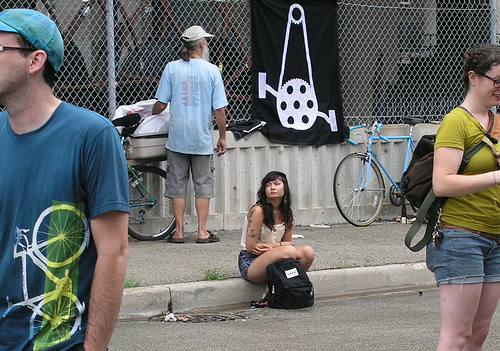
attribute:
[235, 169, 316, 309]
woman — sitting, looking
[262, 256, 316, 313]
backpack — black, sitting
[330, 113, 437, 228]
bicycle — blue, leaning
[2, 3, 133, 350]
man — standing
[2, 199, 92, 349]
design — bicycle, bike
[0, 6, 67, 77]
hat — blue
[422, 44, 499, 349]
woman — standing, stnading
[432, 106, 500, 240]
shirt — green, shortsleeved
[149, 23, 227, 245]
old man — standing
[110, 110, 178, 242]
bicycle — leaning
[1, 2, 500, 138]
fence — chain link, metal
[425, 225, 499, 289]
shorts — cutoffs